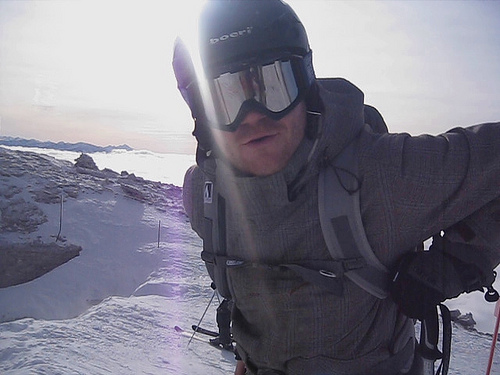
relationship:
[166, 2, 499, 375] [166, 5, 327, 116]
man wearing helmet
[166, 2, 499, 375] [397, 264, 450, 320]
man wearing gloves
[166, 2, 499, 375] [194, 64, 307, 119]
man wearing goggles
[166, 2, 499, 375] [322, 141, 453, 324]
man wearing backpack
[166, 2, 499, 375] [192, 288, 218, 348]
man holding ski pole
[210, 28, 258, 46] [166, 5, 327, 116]
writing on helmet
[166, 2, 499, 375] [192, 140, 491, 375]
man wearing jacket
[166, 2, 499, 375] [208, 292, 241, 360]
man wearing pants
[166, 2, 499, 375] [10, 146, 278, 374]
man standing on top of snow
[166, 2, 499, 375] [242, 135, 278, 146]
man has lips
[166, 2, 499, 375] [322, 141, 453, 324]
man carrying backpack